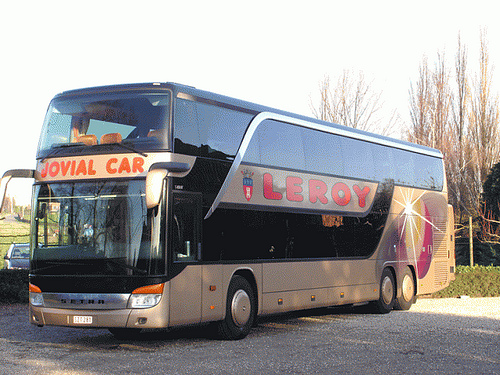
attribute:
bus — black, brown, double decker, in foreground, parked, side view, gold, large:
[27, 84, 458, 333]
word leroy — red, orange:
[260, 169, 370, 213]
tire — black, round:
[221, 279, 256, 339]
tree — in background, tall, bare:
[307, 68, 399, 142]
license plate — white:
[72, 313, 94, 324]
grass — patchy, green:
[2, 208, 68, 278]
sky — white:
[0, 2, 499, 216]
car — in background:
[7, 239, 45, 271]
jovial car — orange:
[37, 158, 148, 179]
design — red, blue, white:
[241, 171, 257, 202]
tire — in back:
[376, 269, 397, 315]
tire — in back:
[392, 266, 419, 312]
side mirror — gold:
[142, 160, 191, 208]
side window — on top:
[177, 105, 252, 155]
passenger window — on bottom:
[214, 208, 285, 260]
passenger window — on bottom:
[277, 215, 376, 260]